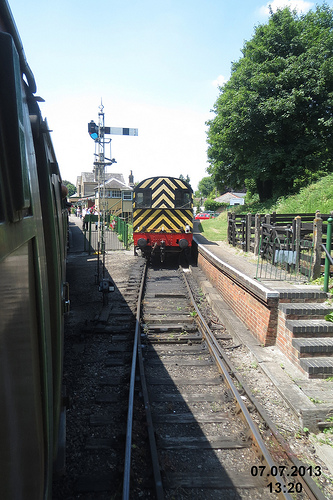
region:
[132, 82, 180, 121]
blue and white skies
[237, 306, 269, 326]
red bricks on side of track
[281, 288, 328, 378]
steps leading up to platform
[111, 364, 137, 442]
blue color on the track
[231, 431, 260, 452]
rust on side of track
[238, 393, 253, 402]
small white stone between tracks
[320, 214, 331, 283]
long green post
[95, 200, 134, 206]
yellow paint on the wall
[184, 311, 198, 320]
small green plant on track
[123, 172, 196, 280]
large train on the tracks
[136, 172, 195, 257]
black and yellow part of train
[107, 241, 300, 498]
black train tracks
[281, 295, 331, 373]
ladders of starway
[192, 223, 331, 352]
small bricked platform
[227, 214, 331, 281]
little wooden fence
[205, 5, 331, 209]
big green bush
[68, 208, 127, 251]
green fence next to black and yellow train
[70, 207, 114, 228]
a bun ch of people behind green fence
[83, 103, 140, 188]
control tower in platform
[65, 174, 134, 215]
yellowcake house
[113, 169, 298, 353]
a train on a track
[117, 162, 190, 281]
a black and yellow train on a track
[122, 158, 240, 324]
a balck and yellow train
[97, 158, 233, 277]
a train with black and yellow stripes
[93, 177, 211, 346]
tracks with a train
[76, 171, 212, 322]
train tracks with a train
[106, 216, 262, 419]
train tracks on the ground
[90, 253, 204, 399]
rocks around the train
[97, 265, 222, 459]
rocks surrounding a train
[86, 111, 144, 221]
a light on a pole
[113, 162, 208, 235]
The train has yellow and black stripes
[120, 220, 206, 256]
The bottom of the train is red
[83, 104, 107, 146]
The light is blue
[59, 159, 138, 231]
The building is yellow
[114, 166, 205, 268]
The train is on the tracks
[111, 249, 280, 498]
These are train tracks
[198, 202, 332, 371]
This is a train stop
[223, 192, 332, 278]
A wooden gate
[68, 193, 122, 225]
People in the background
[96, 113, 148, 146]
Blue and white train sign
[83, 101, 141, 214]
control tower on platform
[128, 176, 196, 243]
black and yellow back part of train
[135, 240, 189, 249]
two small back lights of train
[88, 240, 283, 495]
gray rusty train tracks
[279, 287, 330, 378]
ladders of starway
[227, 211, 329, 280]
little brown wooden fence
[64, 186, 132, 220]
yellow house behind fence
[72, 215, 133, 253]
green metal fence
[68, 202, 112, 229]
a bunch of people on platform behind fence